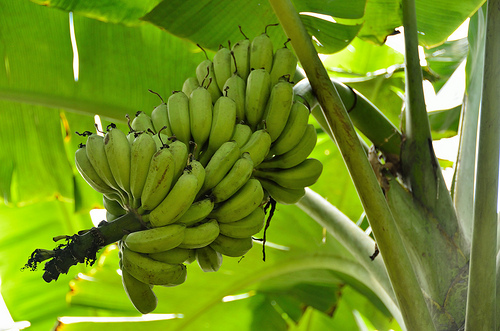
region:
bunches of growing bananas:
[60, 31, 321, 311]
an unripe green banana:
[120, 227, 182, 250]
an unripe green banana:
[143, 166, 200, 227]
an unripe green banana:
[137, 142, 174, 219]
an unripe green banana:
[126, 127, 157, 204]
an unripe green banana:
[105, 121, 127, 195]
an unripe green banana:
[83, 125, 124, 213]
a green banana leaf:
[0, 8, 221, 196]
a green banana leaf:
[71, 201, 331, 325]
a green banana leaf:
[349, 0, 481, 51]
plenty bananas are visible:
[101, 80, 299, 322]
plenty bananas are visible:
[64, 114, 216, 276]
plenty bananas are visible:
[100, 111, 181, 228]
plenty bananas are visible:
[164, 132, 304, 304]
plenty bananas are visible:
[94, 48, 204, 220]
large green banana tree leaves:
[1, 0, 111, 212]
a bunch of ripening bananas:
[75, 21, 314, 316]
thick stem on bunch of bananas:
[27, 172, 137, 298]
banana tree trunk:
[315, 70, 475, 329]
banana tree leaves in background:
[320, 7, 463, 127]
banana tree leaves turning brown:
[282, 270, 350, 330]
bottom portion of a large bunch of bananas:
[67, 129, 223, 295]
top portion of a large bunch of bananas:
[208, 22, 327, 192]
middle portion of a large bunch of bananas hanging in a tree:
[125, 65, 287, 260]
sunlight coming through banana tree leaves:
[356, 18, 441, 84]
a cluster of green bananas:
[74, 53, 314, 305]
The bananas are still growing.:
[34, 15, 450, 315]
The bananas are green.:
[22, 32, 464, 310]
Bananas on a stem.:
[25, 35, 430, 300]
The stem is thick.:
[2, 60, 442, 300]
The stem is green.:
[16, 45, 431, 312]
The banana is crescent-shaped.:
[185, 85, 210, 160]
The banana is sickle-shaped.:
[240, 57, 270, 123]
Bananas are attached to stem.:
[98, 121, 159, 222]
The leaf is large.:
[1, 2, 421, 303]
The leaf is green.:
[1, 1, 411, 302]